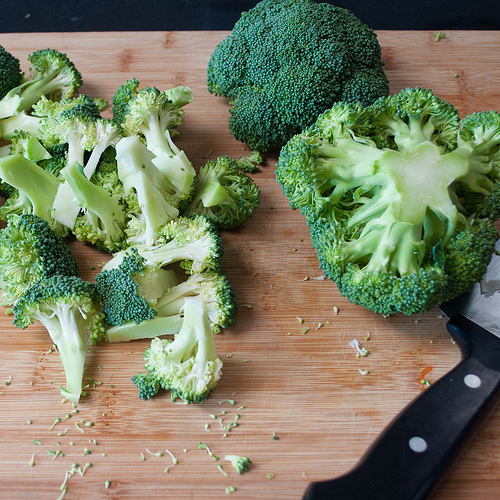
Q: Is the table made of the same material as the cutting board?
A: Yes, both the table and the cutting board are made of wood.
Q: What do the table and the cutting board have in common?
A: The material, both the table and the cutting board are wooden.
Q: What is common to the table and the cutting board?
A: The material, both the table and the cutting board are wooden.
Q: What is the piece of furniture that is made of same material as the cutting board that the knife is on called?
A: The piece of furniture is a table.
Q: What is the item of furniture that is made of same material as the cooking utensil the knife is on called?
A: The piece of furniture is a table.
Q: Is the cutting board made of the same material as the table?
A: Yes, both the cutting board and the table are made of wood.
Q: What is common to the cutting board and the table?
A: The material, both the cutting board and the table are wooden.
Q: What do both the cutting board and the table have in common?
A: The material, both the cutting board and the table are wooden.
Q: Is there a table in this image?
A: Yes, there is a table.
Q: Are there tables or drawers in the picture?
A: Yes, there is a table.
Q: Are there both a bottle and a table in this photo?
A: No, there is a table but no bottles.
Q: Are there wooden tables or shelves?
A: Yes, there is a wood table.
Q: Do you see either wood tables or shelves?
A: Yes, there is a wood table.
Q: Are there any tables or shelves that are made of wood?
A: Yes, the table is made of wood.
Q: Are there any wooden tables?
A: Yes, there is a wood table.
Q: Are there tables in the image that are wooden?
A: Yes, there is a table that is wooden.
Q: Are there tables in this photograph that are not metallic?
A: Yes, there is a wooden table.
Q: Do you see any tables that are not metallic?
A: Yes, there is a wooden table.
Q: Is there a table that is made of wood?
A: Yes, there is a table that is made of wood.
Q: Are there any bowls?
A: No, there are no bowls.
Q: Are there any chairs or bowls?
A: No, there are no bowls or chairs.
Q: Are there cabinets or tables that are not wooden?
A: No, there is a table but it is wooden.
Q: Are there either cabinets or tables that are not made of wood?
A: No, there is a table but it is made of wood.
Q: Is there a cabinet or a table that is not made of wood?
A: No, there is a table but it is made of wood.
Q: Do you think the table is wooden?
A: Yes, the table is wooden.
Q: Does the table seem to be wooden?
A: Yes, the table is wooden.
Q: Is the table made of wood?
A: Yes, the table is made of wood.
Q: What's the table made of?
A: The table is made of wood.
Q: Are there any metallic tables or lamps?
A: No, there is a table but it is wooden.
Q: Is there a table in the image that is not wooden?
A: No, there is a table but it is wooden.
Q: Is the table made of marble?
A: No, the table is made of wood.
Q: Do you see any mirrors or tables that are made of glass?
A: No, there is a table but it is made of wood.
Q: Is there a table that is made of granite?
A: No, there is a table but it is made of wood.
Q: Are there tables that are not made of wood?
A: No, there is a table but it is made of wood.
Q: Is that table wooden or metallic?
A: The table is wooden.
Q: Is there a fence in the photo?
A: No, there are no fences.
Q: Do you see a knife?
A: Yes, there is a knife.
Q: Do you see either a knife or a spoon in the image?
A: Yes, there is a knife.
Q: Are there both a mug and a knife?
A: No, there is a knife but no mugs.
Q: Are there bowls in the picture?
A: No, there are no bowls.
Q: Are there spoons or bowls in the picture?
A: No, there are no bowls or spoons.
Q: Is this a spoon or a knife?
A: This is a knife.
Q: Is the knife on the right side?
A: Yes, the knife is on the right of the image.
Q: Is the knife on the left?
A: No, the knife is on the right of the image.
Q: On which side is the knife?
A: The knife is on the right of the image.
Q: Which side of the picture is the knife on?
A: The knife is on the right of the image.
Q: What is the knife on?
A: The knife is on the cutting board.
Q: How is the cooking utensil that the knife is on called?
A: The cooking utensil is a cutting board.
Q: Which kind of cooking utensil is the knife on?
A: The knife is on the cutting board.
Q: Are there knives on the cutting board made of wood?
A: Yes, there is a knife on the cutting board.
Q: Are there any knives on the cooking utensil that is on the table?
A: Yes, there is a knife on the cutting board.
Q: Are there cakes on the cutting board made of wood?
A: No, there is a knife on the cutting board.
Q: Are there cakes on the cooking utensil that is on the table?
A: No, there is a knife on the cutting board.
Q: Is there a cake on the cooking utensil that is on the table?
A: No, there is a knife on the cutting board.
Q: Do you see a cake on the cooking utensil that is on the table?
A: No, there is a knife on the cutting board.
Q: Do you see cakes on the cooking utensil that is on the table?
A: No, there is a knife on the cutting board.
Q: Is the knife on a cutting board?
A: Yes, the knife is on a cutting board.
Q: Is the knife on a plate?
A: No, the knife is on a cutting board.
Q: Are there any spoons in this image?
A: No, there are no spoons.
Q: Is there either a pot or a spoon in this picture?
A: No, there are no spoons or pots.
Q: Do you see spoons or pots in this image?
A: No, there are no spoons or pots.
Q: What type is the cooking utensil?
A: The cooking utensil is a cutting board.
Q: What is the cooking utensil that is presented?
A: The cooking utensil is a cutting board.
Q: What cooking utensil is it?
A: The cooking utensil is a cutting board.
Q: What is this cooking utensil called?
A: This is a cutting board.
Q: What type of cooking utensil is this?
A: This is a cutting board.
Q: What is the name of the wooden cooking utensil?
A: The cooking utensil is a cutting board.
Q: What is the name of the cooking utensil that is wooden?
A: The cooking utensil is a cutting board.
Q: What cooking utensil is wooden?
A: The cooking utensil is a cutting board.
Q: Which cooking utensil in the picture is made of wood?
A: The cooking utensil is a cutting board.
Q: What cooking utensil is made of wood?
A: The cooking utensil is a cutting board.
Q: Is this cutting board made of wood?
A: Yes, the cutting board is made of wood.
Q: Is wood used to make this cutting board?
A: Yes, the cutting board is made of wood.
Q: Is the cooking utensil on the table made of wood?
A: Yes, the cutting board is made of wood.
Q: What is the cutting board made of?
A: The cutting board is made of wood.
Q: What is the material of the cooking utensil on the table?
A: The cutting board is made of wood.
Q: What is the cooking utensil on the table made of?
A: The cutting board is made of wood.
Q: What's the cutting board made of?
A: The cutting board is made of wood.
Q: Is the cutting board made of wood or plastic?
A: The cutting board is made of wood.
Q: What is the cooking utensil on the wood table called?
A: The cooking utensil is a cutting board.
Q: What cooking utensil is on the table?
A: The cooking utensil is a cutting board.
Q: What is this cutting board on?
A: The cutting board is on the table.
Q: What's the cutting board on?
A: The cutting board is on the table.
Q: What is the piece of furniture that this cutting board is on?
A: The piece of furniture is a table.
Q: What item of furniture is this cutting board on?
A: The cutting board is on the table.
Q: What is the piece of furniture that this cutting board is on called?
A: The piece of furniture is a table.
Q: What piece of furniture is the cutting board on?
A: The cutting board is on the table.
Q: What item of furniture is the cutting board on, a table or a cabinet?
A: The cutting board is on a table.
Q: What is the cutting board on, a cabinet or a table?
A: The cutting board is on a table.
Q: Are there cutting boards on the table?
A: Yes, there is a cutting board on the table.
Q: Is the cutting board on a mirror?
A: No, the cutting board is on the table.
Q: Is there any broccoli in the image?
A: Yes, there is broccoli.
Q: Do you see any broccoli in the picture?
A: Yes, there is broccoli.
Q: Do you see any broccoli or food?
A: Yes, there is broccoli.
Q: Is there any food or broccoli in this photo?
A: Yes, there is broccoli.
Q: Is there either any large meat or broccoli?
A: Yes, there is large broccoli.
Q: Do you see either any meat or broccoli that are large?
A: Yes, the broccoli is large.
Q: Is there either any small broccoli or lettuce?
A: Yes, there is small broccoli.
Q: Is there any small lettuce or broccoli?
A: Yes, there is small broccoli.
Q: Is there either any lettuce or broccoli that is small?
A: Yes, the broccoli is small.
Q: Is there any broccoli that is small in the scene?
A: Yes, there is small broccoli.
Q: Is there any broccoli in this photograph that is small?
A: Yes, there is broccoli that is small.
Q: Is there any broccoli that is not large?
A: Yes, there is small broccoli.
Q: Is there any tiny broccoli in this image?
A: Yes, there is tiny broccoli.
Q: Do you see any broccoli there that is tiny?
A: Yes, there is broccoli that is tiny.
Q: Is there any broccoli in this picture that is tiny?
A: Yes, there is broccoli that is tiny.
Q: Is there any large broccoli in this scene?
A: Yes, there is large broccoli.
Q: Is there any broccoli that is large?
A: Yes, there is broccoli that is large.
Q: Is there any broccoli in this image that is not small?
A: Yes, there is large broccoli.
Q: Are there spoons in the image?
A: No, there are no spoons.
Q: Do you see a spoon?
A: No, there are no spoons.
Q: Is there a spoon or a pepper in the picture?
A: No, there are no spoons or peppers.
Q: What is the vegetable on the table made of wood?
A: The vegetable is broccoli.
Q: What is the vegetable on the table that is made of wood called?
A: The vegetable is broccoli.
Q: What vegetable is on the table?
A: The vegetable is broccoli.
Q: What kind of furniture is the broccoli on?
A: The broccoli is on the table.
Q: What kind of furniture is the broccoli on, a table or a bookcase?
A: The broccoli is on a table.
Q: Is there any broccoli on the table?
A: Yes, there is broccoli on the table.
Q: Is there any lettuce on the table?
A: No, there is broccoli on the table.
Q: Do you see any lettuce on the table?
A: No, there is broccoli on the table.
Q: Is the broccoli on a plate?
A: No, the broccoli is on the table.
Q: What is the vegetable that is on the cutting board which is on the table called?
A: The vegetable is broccoli.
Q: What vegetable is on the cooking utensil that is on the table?
A: The vegetable is broccoli.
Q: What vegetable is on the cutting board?
A: The vegetable is broccoli.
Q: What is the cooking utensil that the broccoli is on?
A: The cooking utensil is a cutting board.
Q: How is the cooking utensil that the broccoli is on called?
A: The cooking utensil is a cutting board.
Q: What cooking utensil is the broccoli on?
A: The broccoli is on the cutting board.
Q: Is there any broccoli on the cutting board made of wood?
A: Yes, there is broccoli on the cutting board.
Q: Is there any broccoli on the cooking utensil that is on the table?
A: Yes, there is broccoli on the cutting board.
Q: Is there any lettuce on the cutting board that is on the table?
A: No, there is broccoli on the cutting board.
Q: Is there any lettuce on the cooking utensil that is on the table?
A: No, there is broccoli on the cutting board.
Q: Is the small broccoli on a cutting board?
A: Yes, the broccoli is on a cutting board.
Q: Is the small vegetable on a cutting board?
A: Yes, the broccoli is on a cutting board.